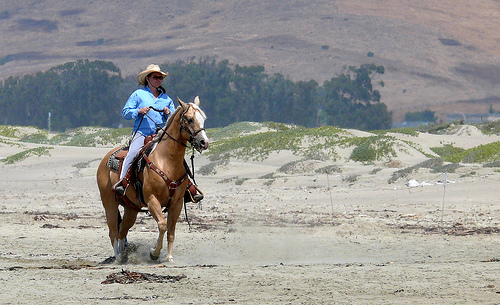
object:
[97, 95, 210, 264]
horse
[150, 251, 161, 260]
hoof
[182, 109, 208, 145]
face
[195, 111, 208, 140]
white shape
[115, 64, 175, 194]
woman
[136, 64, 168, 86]
hat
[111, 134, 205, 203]
stirrups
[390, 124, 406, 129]
water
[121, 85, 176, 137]
shirt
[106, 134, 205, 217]
harness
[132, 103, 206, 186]
reigns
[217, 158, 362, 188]
pile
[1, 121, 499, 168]
plants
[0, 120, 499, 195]
dunes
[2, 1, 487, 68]
sky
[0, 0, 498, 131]
clouds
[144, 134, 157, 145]
saddle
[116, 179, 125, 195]
foot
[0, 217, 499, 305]
sand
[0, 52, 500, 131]
trees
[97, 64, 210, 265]
ridden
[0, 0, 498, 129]
background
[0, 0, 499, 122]
mountain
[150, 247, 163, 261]
feet